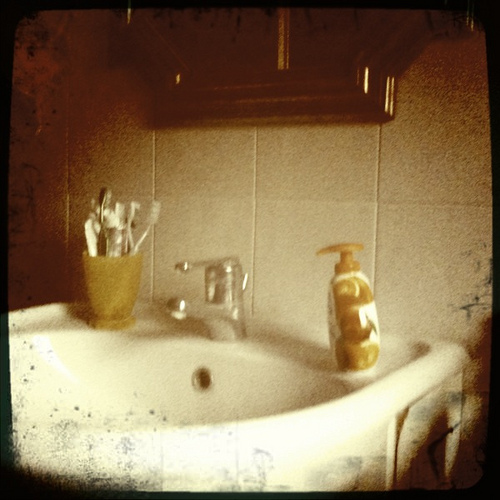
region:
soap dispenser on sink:
[320, 224, 376, 374]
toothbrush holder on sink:
[81, 253, 141, 330]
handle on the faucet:
[165, 254, 257, 284]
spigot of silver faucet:
[164, 295, 184, 322]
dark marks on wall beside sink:
[432, 234, 498, 329]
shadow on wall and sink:
[415, 343, 487, 490]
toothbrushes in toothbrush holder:
[77, 180, 162, 254]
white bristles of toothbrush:
[142, 205, 172, 225]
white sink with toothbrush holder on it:
[14, 283, 419, 486]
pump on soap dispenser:
[317, 242, 366, 265]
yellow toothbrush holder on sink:
[67, 183, 149, 318]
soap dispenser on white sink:
[320, 238, 378, 381]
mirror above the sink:
[122, 9, 407, 111]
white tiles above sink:
[31, 90, 466, 317]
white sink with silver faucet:
[4, 288, 461, 489]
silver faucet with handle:
[166, 253, 254, 338]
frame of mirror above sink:
[109, 3, 439, 125]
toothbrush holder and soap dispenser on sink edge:
[74, 188, 388, 383]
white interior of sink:
[26, 340, 281, 426]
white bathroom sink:
[10, 291, 481, 488]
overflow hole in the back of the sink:
[191, 364, 216, 391]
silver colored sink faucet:
[163, 252, 251, 343]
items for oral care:
[81, 183, 163, 255]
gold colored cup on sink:
[75, 248, 160, 329]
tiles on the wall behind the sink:
[35, 155, 485, 335]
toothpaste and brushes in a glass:
[76, 181, 161, 331]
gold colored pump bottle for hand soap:
[314, 239, 382, 374]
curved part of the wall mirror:
[353, 7, 478, 119]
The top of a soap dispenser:
[314, 233, 371, 263]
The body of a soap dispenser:
[328, 264, 384, 376]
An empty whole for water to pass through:
[183, 363, 224, 393]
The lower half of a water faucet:
[170, 285, 255, 347]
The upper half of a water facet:
[172, 238, 249, 298]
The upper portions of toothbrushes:
[115, 195, 170, 227]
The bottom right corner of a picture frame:
[347, 61, 408, 126]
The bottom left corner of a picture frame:
[138, 67, 189, 138]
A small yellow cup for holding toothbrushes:
[80, 254, 142, 329]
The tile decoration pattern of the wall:
[176, 132, 488, 235]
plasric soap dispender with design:
[312, 241, 388, 376]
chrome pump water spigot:
[164, 258, 256, 345]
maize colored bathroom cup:
[83, 251, 140, 333]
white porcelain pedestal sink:
[5, 299, 480, 499]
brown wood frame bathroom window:
[100, 7, 477, 124]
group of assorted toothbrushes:
[80, 187, 160, 255]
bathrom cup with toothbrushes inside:
[77, 191, 157, 331]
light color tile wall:
[9, 16, 494, 363]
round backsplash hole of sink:
[187, 365, 222, 392]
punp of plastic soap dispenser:
[317, 241, 366, 273]